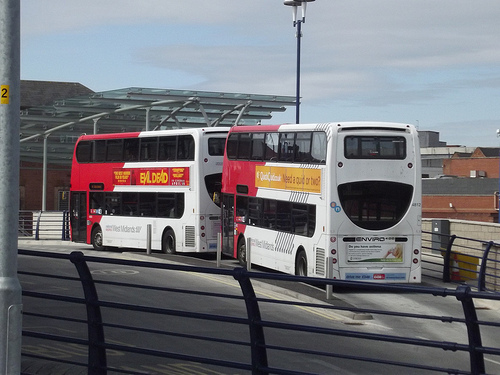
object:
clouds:
[438, 111, 497, 148]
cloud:
[288, 68, 387, 103]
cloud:
[307, 0, 498, 46]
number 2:
[1, 88, 8, 100]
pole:
[0, 1, 23, 375]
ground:
[0, 236, 500, 375]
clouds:
[127, 46, 292, 83]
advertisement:
[112, 166, 189, 186]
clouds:
[300, 68, 385, 104]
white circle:
[90, 268, 139, 277]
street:
[1, 233, 499, 371]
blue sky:
[18, 0, 498, 148]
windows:
[153, 134, 180, 163]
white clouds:
[206, 70, 292, 93]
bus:
[61, 124, 232, 257]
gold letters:
[140, 172, 146, 183]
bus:
[218, 122, 426, 290]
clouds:
[398, 45, 498, 76]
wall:
[419, 193, 500, 224]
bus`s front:
[68, 125, 199, 252]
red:
[70, 164, 105, 179]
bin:
[445, 250, 480, 281]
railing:
[422, 230, 499, 294]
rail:
[21, 249, 499, 373]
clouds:
[318, 0, 436, 32]